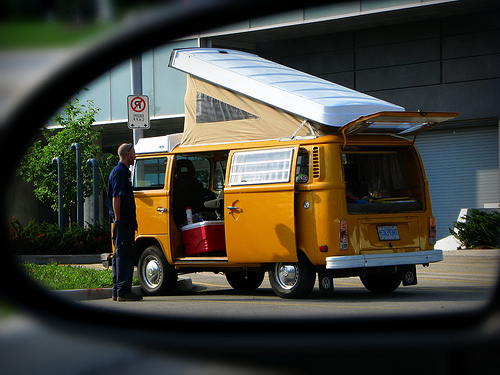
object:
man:
[105, 142, 142, 303]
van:
[107, 46, 446, 290]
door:
[225, 147, 298, 267]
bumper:
[326, 247, 449, 269]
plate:
[375, 223, 401, 240]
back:
[328, 132, 437, 254]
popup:
[166, 47, 413, 139]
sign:
[128, 94, 151, 128]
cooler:
[181, 218, 226, 251]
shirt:
[105, 162, 141, 224]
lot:
[23, 250, 498, 336]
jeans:
[111, 226, 136, 289]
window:
[339, 106, 453, 144]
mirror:
[6, 7, 500, 370]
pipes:
[46, 145, 105, 224]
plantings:
[14, 217, 108, 262]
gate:
[413, 123, 497, 241]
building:
[18, 4, 496, 257]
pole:
[130, 54, 145, 143]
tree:
[22, 98, 118, 227]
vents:
[307, 142, 325, 182]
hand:
[111, 210, 122, 221]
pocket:
[112, 216, 119, 226]